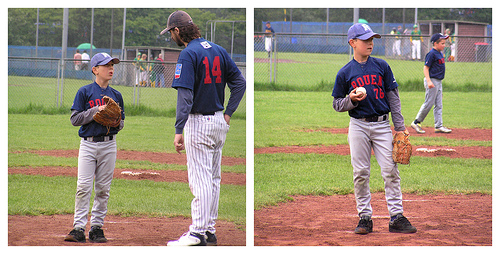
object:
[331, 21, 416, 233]
baseball player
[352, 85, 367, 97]
baseball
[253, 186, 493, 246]
sand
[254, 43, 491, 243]
ground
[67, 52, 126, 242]
person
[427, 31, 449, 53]
person's head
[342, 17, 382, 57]
person's head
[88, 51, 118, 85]
person's head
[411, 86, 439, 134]
leg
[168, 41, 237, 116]
shirt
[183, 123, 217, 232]
leg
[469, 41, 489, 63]
trash can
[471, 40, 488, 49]
red lid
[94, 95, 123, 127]
glove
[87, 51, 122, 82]
head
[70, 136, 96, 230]
leg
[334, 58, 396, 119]
jersey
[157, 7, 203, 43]
head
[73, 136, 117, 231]
baseball pants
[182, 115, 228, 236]
baseball pants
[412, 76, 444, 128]
baseball pants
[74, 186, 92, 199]
knees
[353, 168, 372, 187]
knees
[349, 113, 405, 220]
pants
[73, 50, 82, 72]
people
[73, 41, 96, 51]
umbrella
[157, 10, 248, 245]
coach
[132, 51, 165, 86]
other team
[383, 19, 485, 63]
bullpen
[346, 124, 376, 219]
leg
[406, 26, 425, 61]
players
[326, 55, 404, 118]
shirts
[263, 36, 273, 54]
pants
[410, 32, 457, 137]
person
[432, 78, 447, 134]
leg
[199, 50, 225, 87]
number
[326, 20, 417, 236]
pitcher